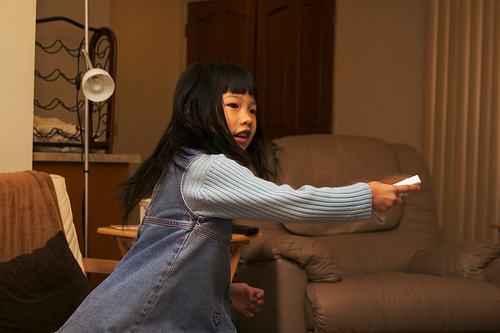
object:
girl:
[53, 60, 423, 333]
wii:
[371, 172, 420, 215]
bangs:
[217, 63, 260, 98]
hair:
[107, 59, 285, 231]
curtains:
[425, 0, 499, 246]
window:
[420, 0, 498, 245]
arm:
[202, 160, 374, 220]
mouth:
[233, 128, 251, 142]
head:
[172, 62, 257, 153]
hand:
[364, 180, 422, 214]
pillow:
[0, 117, 91, 230]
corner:
[48, 229, 70, 244]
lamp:
[80, 68, 116, 101]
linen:
[33, 113, 101, 154]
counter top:
[31, 153, 145, 163]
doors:
[186, 1, 334, 143]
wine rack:
[35, 16, 118, 153]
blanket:
[0, 169, 95, 333]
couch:
[0, 170, 122, 333]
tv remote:
[231, 221, 261, 238]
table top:
[98, 223, 264, 243]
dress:
[54, 146, 240, 331]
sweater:
[182, 148, 372, 221]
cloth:
[370, 175, 421, 225]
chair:
[232, 134, 499, 333]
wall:
[1, 1, 423, 182]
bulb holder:
[90, 75, 101, 81]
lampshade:
[82, 68, 116, 102]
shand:
[76, 61, 97, 266]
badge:
[212, 310, 221, 323]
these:
[225, 101, 258, 117]